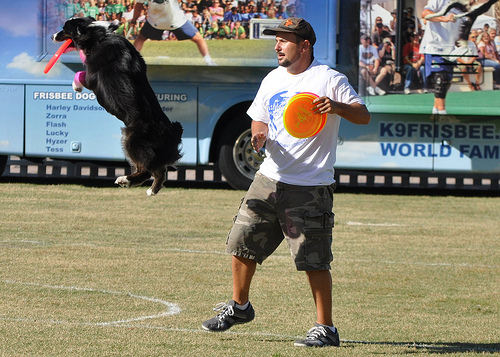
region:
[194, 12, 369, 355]
Man is playing frisbee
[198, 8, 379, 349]
Man holding holding an orange frisbee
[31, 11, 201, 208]
Black dog jumping in the air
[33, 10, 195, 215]
Black dog has a frisbee in his mouth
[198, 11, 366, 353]
Man wears white shirt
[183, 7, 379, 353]
Man wears grey cap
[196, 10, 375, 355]
Man wears grey shoes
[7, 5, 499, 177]
A blue bus behind player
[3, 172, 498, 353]
Field has grass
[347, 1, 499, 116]
Picture on bus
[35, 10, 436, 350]
Playful dog with master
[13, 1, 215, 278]
A dog catching a frisbee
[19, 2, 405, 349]
Frisbee dog entertainment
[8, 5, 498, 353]
Exciting frisbee show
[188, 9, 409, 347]
A man playing frisbee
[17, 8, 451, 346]
Canine dog frisbee show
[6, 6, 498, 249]
World famous K9 Frisbee Show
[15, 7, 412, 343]
A dog and K9 crew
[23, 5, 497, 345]
A dog and man on the playground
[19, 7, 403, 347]
Frisbee training for dogs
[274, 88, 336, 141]
AN ORANGE FRISBEE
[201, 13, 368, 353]
MAN HOLDING A FRISBEE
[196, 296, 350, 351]
A PAIR OF SNEAKERS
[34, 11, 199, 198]
A DOG JUMPING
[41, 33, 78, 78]
A RED FRISBEE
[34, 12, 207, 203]
DOG WITH A FRISBEE IN IT'S MOUTH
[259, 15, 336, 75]
A HAT ON A MAN'S HEAD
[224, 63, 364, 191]
A WHITE TEE SHIRT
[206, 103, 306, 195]
A BLACK BUS WHEEL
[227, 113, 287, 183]
A METAL HUB CAP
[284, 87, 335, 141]
Frisbees in a man's hand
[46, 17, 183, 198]
dog jumping in the air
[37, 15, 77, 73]
Frisbee being caught by dog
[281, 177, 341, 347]
left leg of man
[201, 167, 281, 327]
right leg of man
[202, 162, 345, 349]
lower torso of man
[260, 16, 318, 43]
hat on a man's head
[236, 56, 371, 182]
white t-shirt with blue lettering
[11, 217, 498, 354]
white lines on green grass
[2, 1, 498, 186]
bus advertising frisbee competition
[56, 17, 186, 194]
black dog jumping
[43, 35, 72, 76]
red frisbee in dogs mouth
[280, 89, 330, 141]
three frisbees in mans hand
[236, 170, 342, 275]
camoflage shorts worn by man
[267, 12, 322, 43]
brown baseball hat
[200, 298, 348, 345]
grey tennis shoes with white stripes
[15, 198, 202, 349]
green grassy area with white stripes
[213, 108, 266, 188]
black tire on background vehicle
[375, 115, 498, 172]
k9 frisbee world fam sign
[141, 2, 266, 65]
picture on background vehicle